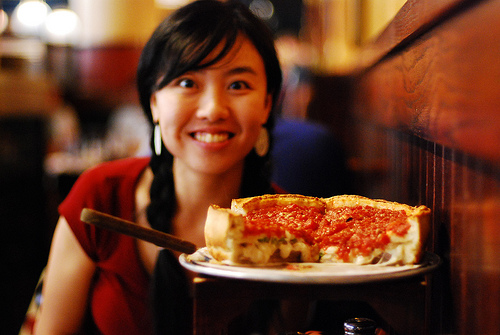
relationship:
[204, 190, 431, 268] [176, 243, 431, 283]
pizza on plate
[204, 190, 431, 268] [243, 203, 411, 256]
pizza has sauce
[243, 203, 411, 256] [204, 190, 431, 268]
sauce on top of pizza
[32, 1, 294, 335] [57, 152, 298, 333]
woman wearing shirt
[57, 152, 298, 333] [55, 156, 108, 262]
shirt has sleeve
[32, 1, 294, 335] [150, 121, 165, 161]
woman wearing earring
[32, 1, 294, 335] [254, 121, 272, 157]
woman wearing earring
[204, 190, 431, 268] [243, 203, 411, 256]
pizza covered in sauce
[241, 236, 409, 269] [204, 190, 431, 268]
cheese inside of pizza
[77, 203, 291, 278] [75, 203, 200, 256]
utensil has handle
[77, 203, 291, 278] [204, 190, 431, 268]
utensil under pizza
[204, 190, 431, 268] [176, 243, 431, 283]
pizza on top of plate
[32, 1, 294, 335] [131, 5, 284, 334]
woman has hair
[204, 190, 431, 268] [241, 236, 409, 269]
pizza stuffed with cheese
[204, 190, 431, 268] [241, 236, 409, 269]
pizza filled with cheese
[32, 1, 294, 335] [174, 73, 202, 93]
woman has eye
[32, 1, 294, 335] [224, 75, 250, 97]
woman has eye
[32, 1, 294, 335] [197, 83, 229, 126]
woman has nose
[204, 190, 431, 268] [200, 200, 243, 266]
pizza has crust